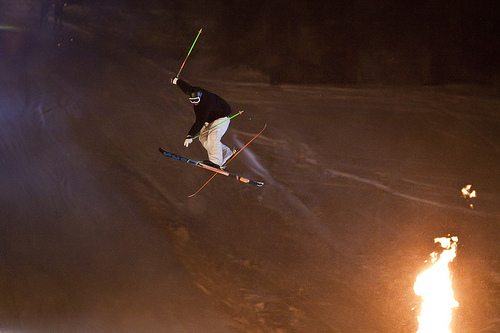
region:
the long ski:
[154, 144, 264, 196]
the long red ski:
[175, 120, 271, 199]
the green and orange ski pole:
[172, 24, 207, 81]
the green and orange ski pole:
[185, 105, 246, 152]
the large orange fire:
[399, 229, 459, 327]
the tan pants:
[195, 113, 235, 168]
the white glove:
[170, 75, 181, 83]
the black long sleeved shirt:
[174, 78, 235, 135]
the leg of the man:
[200, 113, 232, 161]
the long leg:
[199, 120, 233, 162]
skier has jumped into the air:
[156, 15, 274, 212]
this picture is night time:
[0, 2, 495, 330]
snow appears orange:
[0, 235, 497, 320]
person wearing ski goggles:
[170, 75, 235, 180]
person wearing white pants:
[175, 73, 243, 164]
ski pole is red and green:
[175, 22, 200, 85]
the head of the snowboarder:
[188, 86, 202, 103]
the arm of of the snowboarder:
[177, 79, 194, 94]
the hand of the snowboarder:
[182, 137, 192, 144]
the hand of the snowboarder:
[170, 73, 180, 84]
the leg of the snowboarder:
[194, 120, 233, 157]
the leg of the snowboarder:
[206, 115, 224, 164]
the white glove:
[168, 75, 180, 85]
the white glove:
[182, 135, 192, 146]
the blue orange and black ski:
[157, 143, 262, 187]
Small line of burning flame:
[408, 225, 473, 332]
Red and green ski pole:
[170, 20, 202, 87]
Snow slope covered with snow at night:
[7, 3, 498, 328]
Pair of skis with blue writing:
[155, 146, 266, 188]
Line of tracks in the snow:
[92, 123, 317, 331]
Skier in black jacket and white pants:
[151, 23, 278, 192]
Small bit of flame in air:
[456, 181, 480, 212]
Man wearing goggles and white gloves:
[165, 73, 254, 170]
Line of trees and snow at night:
[76, 3, 493, 95]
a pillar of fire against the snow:
[410, 180, 476, 331]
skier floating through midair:
[155, 75, 270, 197]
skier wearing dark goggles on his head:
[185, 92, 200, 102]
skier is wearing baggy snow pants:
[195, 115, 235, 165]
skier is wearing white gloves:
[170, 71, 191, 146]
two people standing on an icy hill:
[35, 0, 70, 40]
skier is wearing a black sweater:
[172, 75, 228, 136]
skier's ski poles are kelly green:
[172, 23, 245, 145]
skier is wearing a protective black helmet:
[186, 85, 204, 99]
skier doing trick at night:
[140, 40, 279, 198]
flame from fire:
[389, 229, 462, 316]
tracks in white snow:
[30, 232, 75, 259]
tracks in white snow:
[196, 299, 230, 316]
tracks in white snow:
[110, 200, 144, 231]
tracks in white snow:
[109, 259, 160, 308]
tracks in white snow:
[305, 113, 367, 166]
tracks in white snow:
[65, 134, 95, 168]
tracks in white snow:
[59, 216, 99, 246]